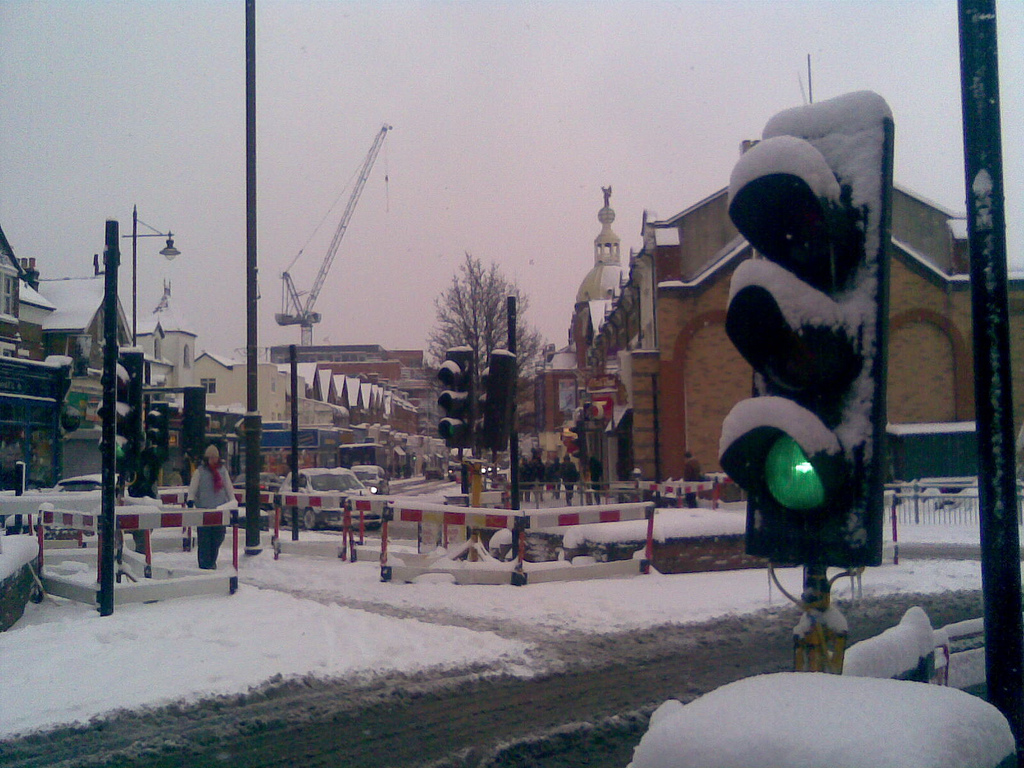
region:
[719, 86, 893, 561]
snow covered electric traffic signal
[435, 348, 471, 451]
snow covered electric traffic signal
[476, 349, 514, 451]
snow covered electric traffic signal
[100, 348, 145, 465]
snow covered electric traffic signal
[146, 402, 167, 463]
snow covered electric traffic signal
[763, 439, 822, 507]
a lit green traffic light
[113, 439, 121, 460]
a lit green traffic light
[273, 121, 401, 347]
a tall crane in distance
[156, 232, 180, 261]
an overhead street light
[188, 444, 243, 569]
a person walking in snow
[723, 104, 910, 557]
black traffic signal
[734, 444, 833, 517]
green light on the traffic signal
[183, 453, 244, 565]
person walking in the snow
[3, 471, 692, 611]
red and white barries around the sidewalk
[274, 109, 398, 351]
crane behind the buildings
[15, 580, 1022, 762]
sludgy street behind the green light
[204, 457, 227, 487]
red scarf person is wearing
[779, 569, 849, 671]
pole the traffic signal is on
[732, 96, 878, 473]
snow covering the traffic signal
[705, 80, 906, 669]
a traffic light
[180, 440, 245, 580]
person wearing a red scarf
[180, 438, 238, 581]
person wearing blue pants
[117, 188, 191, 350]
a street lamp on a post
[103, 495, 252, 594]
a red and white barrier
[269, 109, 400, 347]
a large crane for lifting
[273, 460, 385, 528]
a white car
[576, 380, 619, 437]
a red and white flag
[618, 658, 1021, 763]
a patch of snow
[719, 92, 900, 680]
traffic light covered in snow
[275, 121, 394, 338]
tall crane is up in the air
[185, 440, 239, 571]
woman is walking in snow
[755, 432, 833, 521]
green light on traffic sign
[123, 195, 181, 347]
tall street light is off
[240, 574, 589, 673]
pathway made in snow by footprints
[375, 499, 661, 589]
red and white barrier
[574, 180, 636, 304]
dome on top of a building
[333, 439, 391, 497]
bus is driving down the road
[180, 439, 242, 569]
woman is wearing winter gear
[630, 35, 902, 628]
the traffic light is green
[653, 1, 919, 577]
the traffic light is covered in snow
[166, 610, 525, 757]
the snow is deep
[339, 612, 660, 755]
the road is slushy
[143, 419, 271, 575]
a person is walking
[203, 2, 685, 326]
the sky is overcast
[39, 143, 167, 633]
the pole is black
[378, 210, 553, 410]
the tree is bare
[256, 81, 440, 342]
a crane in the background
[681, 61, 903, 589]
the traffic light is black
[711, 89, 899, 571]
snow covered traffic light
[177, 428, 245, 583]
warmly dressed woman waiting to cross street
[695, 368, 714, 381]
A brick in a wall.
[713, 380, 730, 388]
A brick in a wall.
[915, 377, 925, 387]
A brick in a wall.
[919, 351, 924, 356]
A brick in a wall.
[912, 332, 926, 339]
A brick in a wall.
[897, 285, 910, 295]
A brick in a wall.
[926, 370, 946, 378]
A brick in a wall.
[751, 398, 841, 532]
green traffic light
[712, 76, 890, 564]
black plastic traffic light frame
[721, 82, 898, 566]
snow on top of traffic light